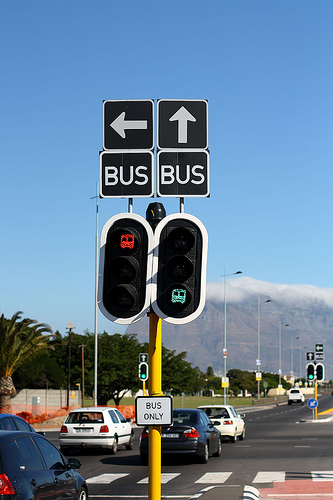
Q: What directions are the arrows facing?
A: Left and up.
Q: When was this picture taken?
A: Daytime.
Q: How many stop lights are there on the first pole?
A: Two.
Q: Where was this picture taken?
A: By a street.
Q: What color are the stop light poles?
A: Yellow.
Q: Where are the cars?
A: On the road.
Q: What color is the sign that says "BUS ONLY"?
A: White.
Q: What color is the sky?
A: Blue.